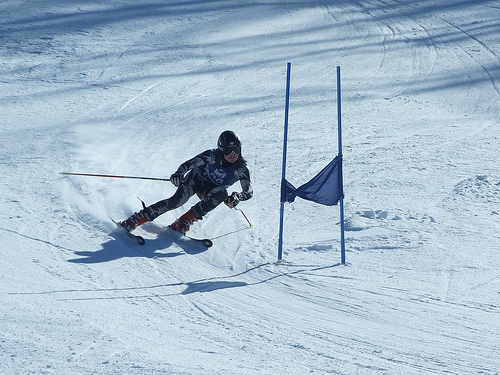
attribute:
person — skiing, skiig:
[117, 131, 252, 237]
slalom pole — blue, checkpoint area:
[276, 62, 292, 261]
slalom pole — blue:
[336, 66, 347, 266]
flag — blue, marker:
[281, 157, 340, 204]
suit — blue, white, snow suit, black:
[149, 151, 253, 219]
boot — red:
[121, 211, 147, 231]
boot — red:
[173, 211, 196, 234]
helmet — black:
[219, 132, 239, 147]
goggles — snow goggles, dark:
[221, 145, 241, 154]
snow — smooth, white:
[1, 2, 499, 374]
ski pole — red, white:
[61, 171, 171, 183]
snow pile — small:
[342, 210, 436, 233]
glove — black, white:
[169, 174, 185, 187]